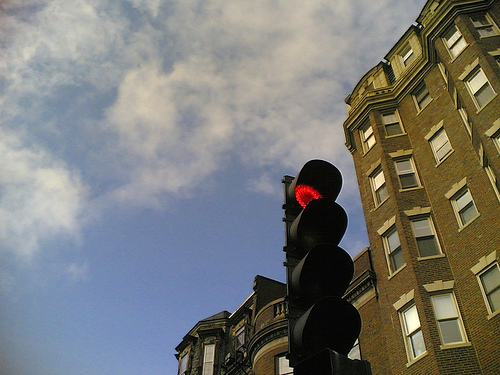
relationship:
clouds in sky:
[0, 0, 424, 308] [23, 17, 406, 321]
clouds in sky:
[0, 0, 424, 308] [3, 0, 283, 297]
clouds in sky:
[0, 0, 424, 308] [6, 3, 287, 268]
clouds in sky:
[117, 63, 195, 162] [15, 18, 364, 328]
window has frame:
[424, 118, 454, 167] [382, 144, 427, 197]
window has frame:
[427, 290, 473, 352] [422, 275, 474, 352]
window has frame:
[422, 114, 454, 169] [416, 115, 460, 173]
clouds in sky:
[0, 0, 424, 308] [5, 7, 411, 374]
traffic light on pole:
[279, 157, 371, 374] [290, 347, 368, 372]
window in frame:
[446, 178, 480, 233] [444, 173, 464, 198]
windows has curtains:
[396, 286, 466, 361] [438, 295, 454, 339]